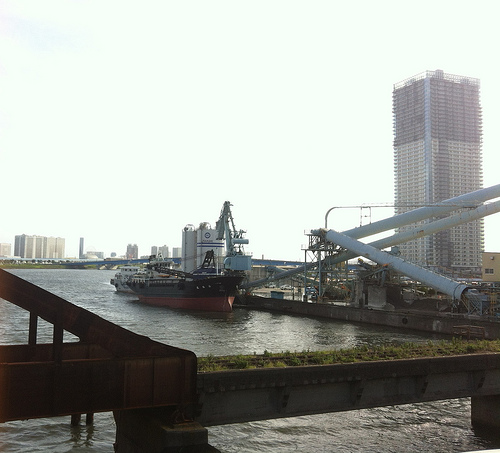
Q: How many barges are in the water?
A: One.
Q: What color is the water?
A: Gray.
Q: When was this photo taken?
A: During the day.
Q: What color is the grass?
A: Green.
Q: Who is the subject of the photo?
A: The boat.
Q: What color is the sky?
A: White.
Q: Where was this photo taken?
A: In a harbor.